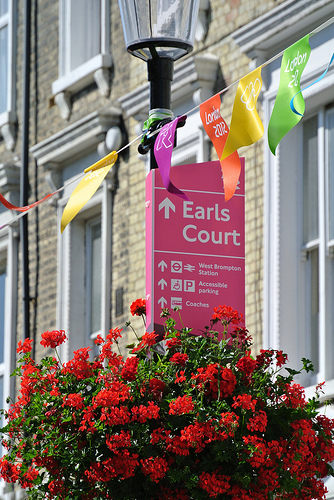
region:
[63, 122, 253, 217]
multi colored banners hanging from a line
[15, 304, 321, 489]
a bush of red flowers at base of red sign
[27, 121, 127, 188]
ornate cement over doorway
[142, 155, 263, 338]
red sign with white lettering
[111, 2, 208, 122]
street lamp on black pole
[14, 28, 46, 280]
long gutter running down side of building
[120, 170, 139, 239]
yellow brick of building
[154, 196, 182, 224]
arrow pointing up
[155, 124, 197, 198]
purple pennant with white lettering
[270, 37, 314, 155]
green pennant with white lettering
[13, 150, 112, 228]
yellow triangular flag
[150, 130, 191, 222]
purple triangular flag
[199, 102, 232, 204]
orange triangular flag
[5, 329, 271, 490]
bush of red flowers with green leaves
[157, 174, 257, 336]
pink sign with white writing on it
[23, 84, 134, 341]
brick building with white window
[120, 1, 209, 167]
street light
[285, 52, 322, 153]
lime green triangular flag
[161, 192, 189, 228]
white upward facing arrow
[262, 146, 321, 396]
white outline of window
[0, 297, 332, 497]
lots of red flowers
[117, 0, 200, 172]
lamp is not lit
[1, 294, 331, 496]
flowers in the sun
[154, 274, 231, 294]
handicap parking sign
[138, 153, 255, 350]
pink sign with white letters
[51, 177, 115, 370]
white window on building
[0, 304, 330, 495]
green leaves and stems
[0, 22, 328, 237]
6 flags hanging on string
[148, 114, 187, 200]
purple flag, white letters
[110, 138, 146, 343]
bricks are tan-colored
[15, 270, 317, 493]
beautiful red geraniums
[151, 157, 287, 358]
the sign is pink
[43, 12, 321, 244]
the pennants are multi colored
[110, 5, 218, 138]
the lamp is above the sign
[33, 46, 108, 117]
the window sills are white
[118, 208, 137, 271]
the building is made from white brick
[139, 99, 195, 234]
this flag is purple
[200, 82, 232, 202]
this flag is orange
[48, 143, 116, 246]
this flag is yellow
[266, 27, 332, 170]
this flag is green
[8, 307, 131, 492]
red flowers with green leaves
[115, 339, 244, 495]
red flowers with green leaves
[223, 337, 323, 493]
red flowers with green leaves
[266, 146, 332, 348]
white window on building exterior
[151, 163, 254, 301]
pink and white sign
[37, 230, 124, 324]
white window on exterior of building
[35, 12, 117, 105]
white window on exterior of building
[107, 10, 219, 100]
clear and black lamp post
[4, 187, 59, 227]
orange and white flag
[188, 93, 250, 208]
orange and white flag